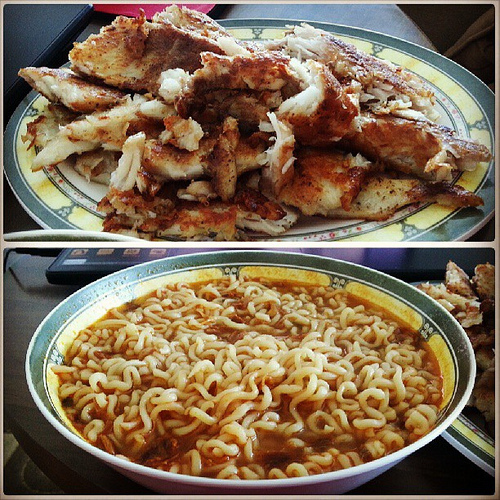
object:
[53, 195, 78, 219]
design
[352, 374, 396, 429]
noodles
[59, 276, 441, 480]
soup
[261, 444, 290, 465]
meat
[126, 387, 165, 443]
noodles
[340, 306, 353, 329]
ramen noodles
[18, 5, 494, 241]
food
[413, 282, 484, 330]
meat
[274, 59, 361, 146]
fish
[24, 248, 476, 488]
bowl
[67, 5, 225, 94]
fish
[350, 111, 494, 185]
meat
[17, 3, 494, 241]
meat pile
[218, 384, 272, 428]
noodles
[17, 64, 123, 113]
fish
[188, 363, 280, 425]
noodles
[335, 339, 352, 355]
noodles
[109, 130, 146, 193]
meat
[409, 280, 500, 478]
plate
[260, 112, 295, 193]
meat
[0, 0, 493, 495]
table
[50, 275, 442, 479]
pattern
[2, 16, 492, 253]
plate